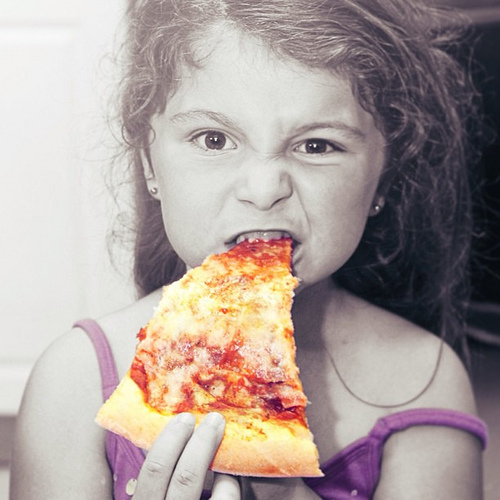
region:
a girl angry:
[12, 0, 490, 497]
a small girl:
[7, 6, 498, 497]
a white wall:
[3, 0, 137, 425]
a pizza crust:
[92, 368, 343, 499]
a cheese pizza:
[93, 232, 348, 492]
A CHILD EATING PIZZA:
[7, 1, 493, 496]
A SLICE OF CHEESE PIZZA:
[91, 234, 330, 486]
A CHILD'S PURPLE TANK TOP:
[68, 313, 488, 498]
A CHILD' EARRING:
[370, 194, 384, 219]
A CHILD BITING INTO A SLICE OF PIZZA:
[10, 4, 493, 496]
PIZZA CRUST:
[90, 373, 327, 484]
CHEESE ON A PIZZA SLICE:
[156, 300, 288, 397]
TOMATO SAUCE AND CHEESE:
[164, 320, 288, 408]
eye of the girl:
[187, 118, 225, 164]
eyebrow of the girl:
[183, 103, 220, 125]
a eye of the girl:
[293, 137, 340, 167]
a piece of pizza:
[96, 256, 320, 486]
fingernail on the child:
[172, 408, 196, 426]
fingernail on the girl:
[195, 412, 227, 429]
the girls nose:
[241, 167, 284, 203]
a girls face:
[143, 46, 387, 298]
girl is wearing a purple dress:
[67, 313, 438, 495]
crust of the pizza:
[120, 385, 306, 470]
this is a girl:
[1, 0, 479, 487]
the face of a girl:
[107, 13, 452, 290]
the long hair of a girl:
[91, 3, 486, 354]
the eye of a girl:
[281, 115, 346, 179]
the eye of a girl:
[172, 96, 262, 181]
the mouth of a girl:
[221, 212, 318, 286]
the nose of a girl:
[234, 161, 291, 219]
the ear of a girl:
[371, 158, 392, 226]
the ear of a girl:
[120, 136, 162, 210]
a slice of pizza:
[94, 242, 326, 482]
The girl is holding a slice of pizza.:
[95, 229, 325, 484]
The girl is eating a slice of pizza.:
[94, 232, 324, 481]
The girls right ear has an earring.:
[145, 184, 161, 197]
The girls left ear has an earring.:
[373, 202, 381, 215]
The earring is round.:
[149, 184, 161, 200]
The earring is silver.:
[148, 187, 160, 194]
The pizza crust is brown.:
[95, 379, 321, 484]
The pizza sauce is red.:
[131, 325, 303, 429]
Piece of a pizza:
[120, 232, 329, 491]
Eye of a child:
[280, 112, 357, 177]